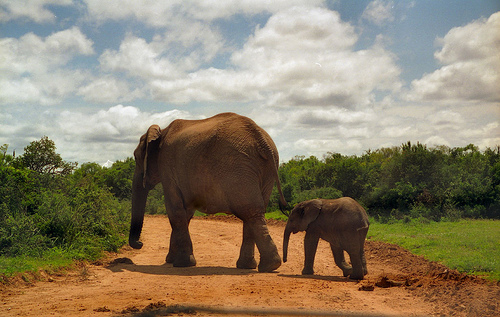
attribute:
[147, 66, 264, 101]
cloud — white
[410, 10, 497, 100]
cloud — white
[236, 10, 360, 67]
cloud — white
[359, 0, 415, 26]
cloud — white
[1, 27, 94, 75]
cloud — white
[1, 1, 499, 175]
sky — blue, patches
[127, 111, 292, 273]
elephant — brown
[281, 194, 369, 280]
elephant — brown, small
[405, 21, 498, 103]
clouds — puffy, grey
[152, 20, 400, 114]
clouds — puffy, grey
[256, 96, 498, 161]
clouds — puffy, grey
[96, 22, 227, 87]
clouds — puffy, grey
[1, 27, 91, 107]
clouds — puffy, grey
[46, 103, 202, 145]
clouds — puffy, grey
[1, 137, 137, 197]
clouds — puffy, grey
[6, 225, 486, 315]
dirt road — crude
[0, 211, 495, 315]
dirt road — red, left-curving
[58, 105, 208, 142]
cloud — white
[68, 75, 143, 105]
cloud — white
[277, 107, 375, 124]
cloud — white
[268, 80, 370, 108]
cloud — white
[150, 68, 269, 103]
cloud — white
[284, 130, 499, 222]
trees — green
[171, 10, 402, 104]
clouds — white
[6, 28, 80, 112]
clouds — white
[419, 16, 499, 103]
clouds — white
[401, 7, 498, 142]
clouds — white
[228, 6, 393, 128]
clouds — white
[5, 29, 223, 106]
clouds — white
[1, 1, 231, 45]
clouds — white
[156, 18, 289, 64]
sky — blue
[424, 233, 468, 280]
grass — small